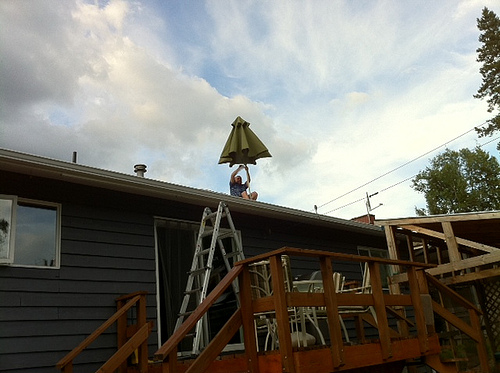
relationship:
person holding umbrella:
[228, 164, 259, 198] [216, 112, 277, 170]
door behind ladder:
[156, 221, 198, 341] [160, 196, 248, 361]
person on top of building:
[228, 164, 259, 198] [1, 142, 498, 369]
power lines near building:
[342, 108, 496, 205] [1, 142, 498, 369]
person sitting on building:
[228, 164, 259, 198] [1, 142, 498, 369]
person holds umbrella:
[228, 164, 259, 198] [216, 112, 277, 170]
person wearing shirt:
[228, 164, 259, 198] [228, 180, 251, 198]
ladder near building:
[160, 196, 248, 361] [1, 142, 498, 369]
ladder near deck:
[160, 196, 248, 361] [48, 239, 497, 368]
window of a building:
[1, 191, 68, 276] [1, 142, 498, 369]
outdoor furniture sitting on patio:
[241, 255, 306, 351] [112, 246, 440, 367]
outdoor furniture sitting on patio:
[286, 277, 320, 346] [112, 246, 440, 367]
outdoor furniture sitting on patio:
[324, 261, 378, 342] [112, 246, 440, 367]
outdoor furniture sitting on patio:
[298, 269, 349, 346] [112, 246, 440, 367]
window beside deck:
[1, 191, 68, 276] [48, 239, 497, 368]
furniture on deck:
[243, 253, 385, 352] [48, 239, 497, 368]